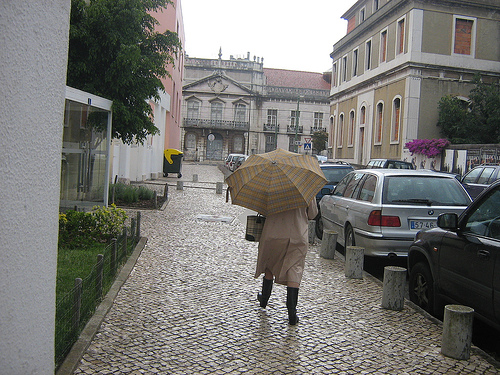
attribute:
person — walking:
[259, 194, 319, 325]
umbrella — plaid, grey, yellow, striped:
[227, 149, 328, 216]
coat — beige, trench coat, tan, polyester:
[255, 195, 319, 287]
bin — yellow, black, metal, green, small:
[163, 147, 182, 177]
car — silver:
[318, 169, 478, 256]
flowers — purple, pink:
[405, 140, 453, 156]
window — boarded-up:
[452, 15, 478, 58]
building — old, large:
[327, 0, 494, 165]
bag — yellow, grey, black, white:
[245, 216, 267, 242]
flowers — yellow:
[58, 206, 122, 236]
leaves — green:
[445, 103, 499, 140]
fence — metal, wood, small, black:
[57, 207, 142, 363]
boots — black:
[257, 279, 300, 321]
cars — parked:
[307, 166, 496, 360]